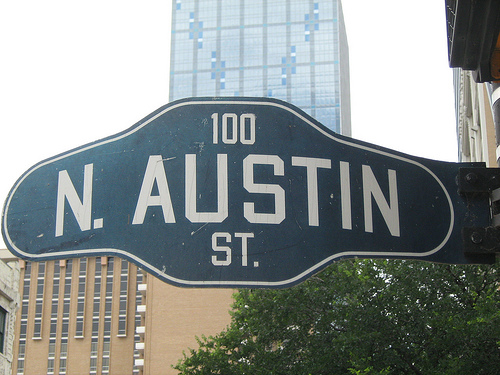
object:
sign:
[0, 95, 456, 291]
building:
[10, 249, 295, 374]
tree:
[172, 249, 499, 374]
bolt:
[463, 169, 484, 185]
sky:
[0, 1, 463, 202]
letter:
[51, 150, 403, 238]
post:
[456, 157, 498, 353]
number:
[203, 109, 262, 149]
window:
[91, 298, 101, 316]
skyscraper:
[164, 6, 351, 190]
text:
[125, 146, 409, 239]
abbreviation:
[206, 231, 261, 269]